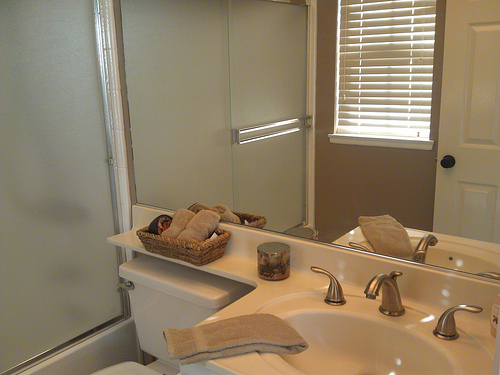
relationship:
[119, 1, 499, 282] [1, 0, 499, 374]
mirror inside bathroom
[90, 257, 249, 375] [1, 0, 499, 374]
toilet inside bathroom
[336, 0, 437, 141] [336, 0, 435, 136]
window has shutters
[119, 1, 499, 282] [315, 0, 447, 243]
mirror has reflection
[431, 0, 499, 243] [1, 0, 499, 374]
door inside bathroom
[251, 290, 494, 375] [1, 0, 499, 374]
sink inside bathroom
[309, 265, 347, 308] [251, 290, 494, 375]
handle on top of sink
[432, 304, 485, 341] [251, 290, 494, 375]
handle on top of sink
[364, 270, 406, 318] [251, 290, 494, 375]
faucet on top of sink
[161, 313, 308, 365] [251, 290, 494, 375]
hand towel next to sink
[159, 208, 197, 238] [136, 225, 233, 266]
towel inside basket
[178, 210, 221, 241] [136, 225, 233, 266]
towel inside basket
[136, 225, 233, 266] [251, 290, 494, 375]
basket to side of sink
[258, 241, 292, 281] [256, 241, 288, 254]
candle has top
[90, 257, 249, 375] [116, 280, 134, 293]
toilet has lever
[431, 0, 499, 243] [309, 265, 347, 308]
door has handle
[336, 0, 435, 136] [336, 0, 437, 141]
shutters covering window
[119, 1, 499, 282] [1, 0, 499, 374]
mirror reflects bathroom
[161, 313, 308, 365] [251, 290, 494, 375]
hand towel on edge of sink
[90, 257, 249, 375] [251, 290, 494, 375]
toilet alongside of sink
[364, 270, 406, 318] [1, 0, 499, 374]
faucet inside bathroom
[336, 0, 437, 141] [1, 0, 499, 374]
window inside bathroom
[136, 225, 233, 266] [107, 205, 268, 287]
basket sitting on shelf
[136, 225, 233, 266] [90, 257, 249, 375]
basket above toilet